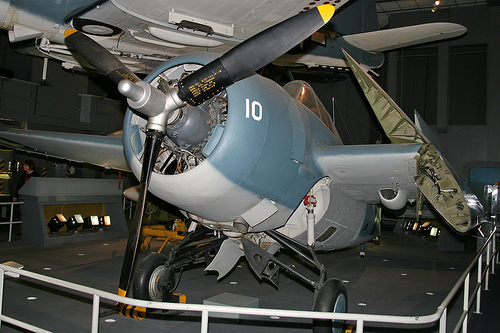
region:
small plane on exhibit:
[47, 33, 453, 303]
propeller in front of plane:
[50, 25, 370, 270]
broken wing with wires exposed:
[326, 131, 481, 208]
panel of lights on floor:
[30, 190, 130, 240]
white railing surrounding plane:
[42, 226, 487, 327]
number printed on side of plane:
[230, 80, 272, 140]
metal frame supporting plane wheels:
[120, 215, 356, 325]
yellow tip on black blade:
[222, 0, 339, 90]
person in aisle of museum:
[7, 145, 48, 205]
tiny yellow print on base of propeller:
[165, 58, 250, 121]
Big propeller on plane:
[51, 4, 351, 304]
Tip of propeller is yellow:
[314, 0, 341, 25]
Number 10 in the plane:
[236, 87, 270, 129]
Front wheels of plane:
[101, 247, 366, 331]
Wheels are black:
[124, 247, 361, 328]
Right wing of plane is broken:
[330, 34, 491, 239]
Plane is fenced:
[11, 3, 498, 331]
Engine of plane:
[104, 56, 241, 180]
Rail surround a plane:
[10, 261, 498, 331]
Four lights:
[45, 208, 120, 243]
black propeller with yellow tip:
[177, 2, 353, 112]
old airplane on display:
[17, 7, 492, 319]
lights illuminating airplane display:
[45, 207, 125, 249]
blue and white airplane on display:
[63, 14, 457, 321]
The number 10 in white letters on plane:
[239, 88, 289, 132]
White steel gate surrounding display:
[450, 203, 499, 330]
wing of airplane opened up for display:
[331, 47, 499, 238]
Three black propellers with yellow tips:
[62, 11, 318, 312]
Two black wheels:
[129, 249, 356, 318]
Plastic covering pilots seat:
[276, 71, 356, 146]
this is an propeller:
[68, 12, 336, 297]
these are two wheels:
[137, 244, 347, 331]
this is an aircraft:
[73, 5, 456, 330]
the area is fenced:
[248, 302, 484, 328]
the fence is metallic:
[223, 308, 363, 315]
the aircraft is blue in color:
[247, 97, 303, 181]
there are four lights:
[49, 210, 116, 229]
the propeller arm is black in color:
[233, 48, 253, 70]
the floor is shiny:
[368, 255, 415, 306]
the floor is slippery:
[371, 257, 428, 304]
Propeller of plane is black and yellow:
[40, 0, 370, 306]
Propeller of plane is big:
[43, 0, 346, 321]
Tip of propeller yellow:
[54, 22, 139, 95]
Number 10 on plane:
[240, 85, 267, 127]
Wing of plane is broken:
[303, 39, 483, 245]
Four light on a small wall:
[47, 201, 121, 241]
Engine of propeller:
[111, 60, 241, 185]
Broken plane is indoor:
[45, 0, 480, 330]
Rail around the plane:
[4, 277, 496, 331]